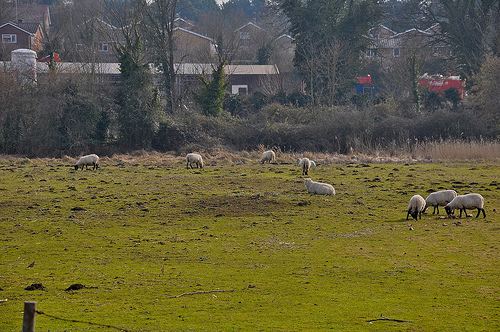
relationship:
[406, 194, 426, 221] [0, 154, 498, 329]
sheep in field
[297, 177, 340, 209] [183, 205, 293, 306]
sheep laying in field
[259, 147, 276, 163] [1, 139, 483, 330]
sheep grazing in field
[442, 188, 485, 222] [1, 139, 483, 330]
sheep grazing in field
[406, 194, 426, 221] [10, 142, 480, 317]
sheep on grass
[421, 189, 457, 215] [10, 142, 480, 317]
sheep on grass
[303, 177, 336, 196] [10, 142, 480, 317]
sheep on grass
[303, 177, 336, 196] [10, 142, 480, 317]
sheep laying on grass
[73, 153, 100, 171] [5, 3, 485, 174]
sheep in background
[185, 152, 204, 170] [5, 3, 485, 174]
grazing sheep in background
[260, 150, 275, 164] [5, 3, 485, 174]
sheep in background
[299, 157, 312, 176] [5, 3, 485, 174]
sheep in background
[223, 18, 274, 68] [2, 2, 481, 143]
house in background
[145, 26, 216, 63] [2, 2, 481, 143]
house in background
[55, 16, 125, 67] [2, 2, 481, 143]
house in background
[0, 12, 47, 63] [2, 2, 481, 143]
house in background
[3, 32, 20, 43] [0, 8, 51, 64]
window on building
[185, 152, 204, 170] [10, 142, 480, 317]
grazing sheep in grass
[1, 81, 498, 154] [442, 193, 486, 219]
bushes behind sheep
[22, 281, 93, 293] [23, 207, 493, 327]
rocks in grass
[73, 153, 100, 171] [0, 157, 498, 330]
sheep eating grass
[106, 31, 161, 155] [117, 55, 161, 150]
tree covered with vine